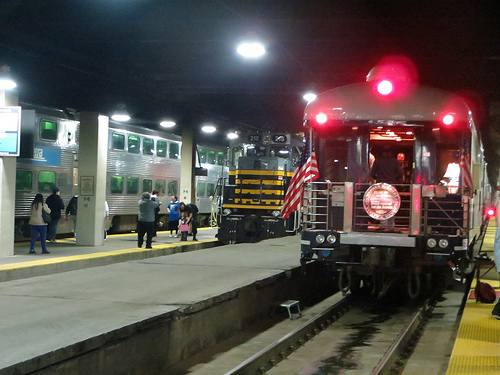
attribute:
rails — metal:
[362, 292, 434, 373]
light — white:
[222, 130, 239, 147]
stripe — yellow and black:
[227, 170, 292, 177]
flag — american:
[273, 143, 319, 223]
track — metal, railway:
[163, 232, 471, 366]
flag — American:
[255, 145, 339, 229]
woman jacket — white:
[18, 190, 50, 263]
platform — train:
[10, 251, 268, 321]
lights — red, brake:
[302, 49, 469, 141]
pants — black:
[133, 216, 157, 248]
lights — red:
[303, 65, 496, 141]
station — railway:
[0, 1, 497, 371]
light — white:
[235, 40, 265, 58]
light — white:
[2, 78, 17, 91]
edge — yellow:
[438, 265, 478, 373]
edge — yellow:
[473, 197, 498, 271]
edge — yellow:
[2, 251, 106, 283]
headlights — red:
[436, 110, 458, 129]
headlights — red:
[372, 71, 399, 102]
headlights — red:
[308, 105, 334, 130]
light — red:
[311, 109, 327, 129]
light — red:
[373, 67, 397, 100]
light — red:
[439, 107, 459, 131]